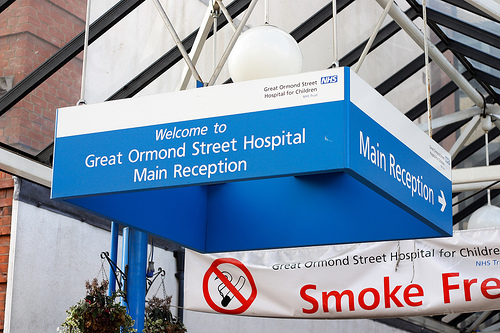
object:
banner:
[180, 225, 499, 319]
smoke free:
[300, 271, 498, 314]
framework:
[155, 2, 225, 83]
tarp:
[24, 273, 71, 315]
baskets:
[60, 279, 185, 331]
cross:
[206, 257, 258, 311]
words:
[82, 119, 309, 182]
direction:
[353, 130, 451, 211]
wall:
[178, 248, 494, 331]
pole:
[120, 227, 150, 330]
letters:
[299, 271, 492, 313]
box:
[48, 68, 454, 254]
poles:
[54, 3, 458, 129]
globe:
[226, 23, 300, 85]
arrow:
[436, 186, 446, 216]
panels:
[95, 6, 488, 96]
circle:
[199, 252, 254, 316]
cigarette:
[210, 268, 245, 311]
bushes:
[56, 275, 184, 330]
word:
[296, 270, 424, 314]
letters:
[432, 261, 476, 303]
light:
[233, 22, 308, 81]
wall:
[1, 4, 81, 181]